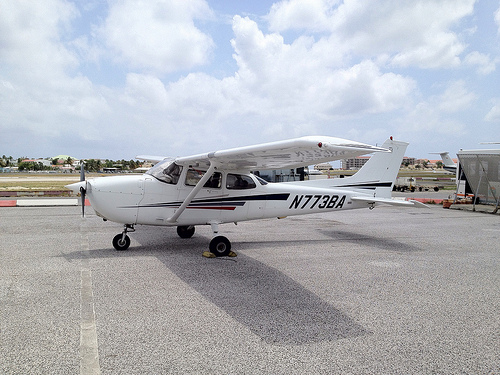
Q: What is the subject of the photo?
A: Plane.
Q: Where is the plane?
A: Tarmac.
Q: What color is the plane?
A: White.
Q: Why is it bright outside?
A: It's daytime.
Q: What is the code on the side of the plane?
A: N773BA.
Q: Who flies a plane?
A: Pilot.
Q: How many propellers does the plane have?
A: One.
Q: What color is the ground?
A: Gray.